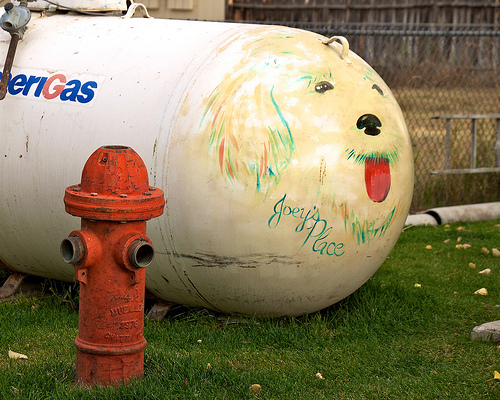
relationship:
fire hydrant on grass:
[59, 147, 169, 387] [15, 235, 497, 393]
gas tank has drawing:
[1, 8, 417, 325] [194, 34, 416, 265]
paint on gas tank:
[338, 111, 395, 205] [1, 8, 417, 325]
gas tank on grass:
[1, 8, 417, 325] [15, 235, 497, 393]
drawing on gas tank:
[194, 34, 416, 265] [1, 8, 417, 325]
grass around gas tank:
[15, 235, 497, 393] [1, 8, 417, 325]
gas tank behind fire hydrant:
[1, 8, 417, 325] [59, 147, 169, 387]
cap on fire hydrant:
[68, 142, 164, 213] [59, 147, 169, 387]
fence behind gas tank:
[331, 16, 500, 210] [1, 8, 417, 325]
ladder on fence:
[430, 104, 499, 182] [331, 16, 500, 210]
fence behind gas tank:
[347, 16, 500, 210] [1, 8, 417, 325]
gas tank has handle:
[1, 8, 417, 325] [118, 2, 184, 50]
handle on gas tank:
[118, 2, 184, 50] [1, 8, 417, 325]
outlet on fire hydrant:
[58, 233, 160, 272] [59, 147, 169, 387]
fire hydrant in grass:
[59, 147, 169, 387] [15, 235, 497, 393]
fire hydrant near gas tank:
[59, 147, 169, 387] [1, 8, 417, 325]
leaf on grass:
[9, 343, 29, 365] [15, 235, 497, 393]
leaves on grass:
[409, 230, 499, 310] [15, 235, 497, 393]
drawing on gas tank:
[200, 67, 406, 261] [1, 8, 417, 325]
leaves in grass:
[409, 230, 499, 310] [15, 235, 497, 393]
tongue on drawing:
[359, 154, 397, 204] [194, 34, 416, 265]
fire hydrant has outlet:
[59, 147, 169, 387] [58, 233, 160, 272]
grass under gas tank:
[15, 235, 497, 393] [1, 8, 417, 325]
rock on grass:
[473, 317, 498, 331] [15, 235, 497, 393]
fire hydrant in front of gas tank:
[59, 147, 169, 387] [1, 8, 417, 325]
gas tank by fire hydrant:
[1, 8, 417, 325] [59, 147, 169, 387]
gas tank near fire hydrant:
[1, 8, 417, 325] [59, 147, 169, 387]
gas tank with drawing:
[1, 8, 417, 325] [194, 34, 416, 265]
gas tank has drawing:
[1, 8, 417, 325] [200, 67, 406, 261]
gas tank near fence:
[1, 8, 417, 325] [331, 16, 500, 210]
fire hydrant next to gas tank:
[59, 147, 169, 387] [1, 8, 417, 325]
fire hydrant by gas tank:
[59, 147, 169, 387] [1, 8, 417, 325]